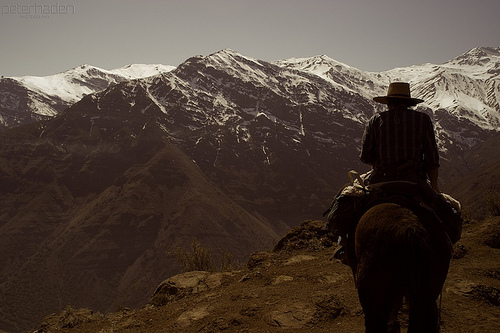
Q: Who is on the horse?
A: A man.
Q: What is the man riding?
A: A horse.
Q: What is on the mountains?
A: Snow.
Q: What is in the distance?
A: Mountains.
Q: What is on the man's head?
A: A cowboy hat.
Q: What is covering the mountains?
A: Snow.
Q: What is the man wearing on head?
A: Cowboy hat.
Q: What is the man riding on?
A: Horse.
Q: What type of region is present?
A: Rocky terrain.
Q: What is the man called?
A: Cowboy.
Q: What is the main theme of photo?
A: Man riding a horse.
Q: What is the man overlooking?
A: Mountains.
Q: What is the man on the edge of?
A: Cliff.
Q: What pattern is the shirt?
A: Plaid.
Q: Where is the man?
A: On a horse.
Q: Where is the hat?
A: On the man's head.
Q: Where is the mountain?
A: In front of the man.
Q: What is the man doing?
A: Riding.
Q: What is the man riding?
A: A horse.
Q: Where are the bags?
A: On the horse.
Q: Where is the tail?
A: On the horse.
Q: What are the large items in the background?
A: Mountains.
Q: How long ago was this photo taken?
A: One year ago.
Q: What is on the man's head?
A: A cowboy hat.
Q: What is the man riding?
A: A horse.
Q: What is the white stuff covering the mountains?
A: Snow.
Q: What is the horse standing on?
A: A rocky outcrop.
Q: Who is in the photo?
A: A man.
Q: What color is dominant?
A: Brown.